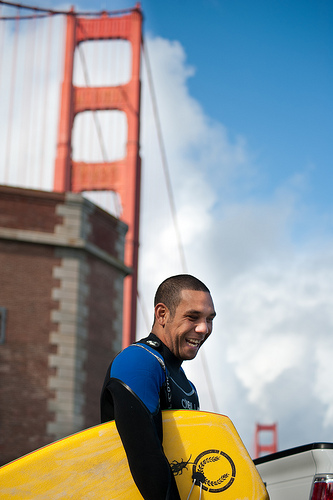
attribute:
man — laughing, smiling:
[91, 259, 216, 411]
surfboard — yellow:
[16, 422, 250, 499]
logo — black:
[185, 451, 236, 498]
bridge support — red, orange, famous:
[69, 10, 132, 192]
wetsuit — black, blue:
[112, 348, 172, 423]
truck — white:
[260, 449, 332, 498]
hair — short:
[162, 277, 211, 298]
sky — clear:
[132, 3, 332, 267]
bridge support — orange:
[254, 426, 279, 452]